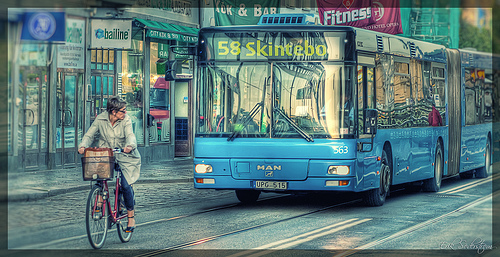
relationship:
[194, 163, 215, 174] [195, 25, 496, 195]
light on bus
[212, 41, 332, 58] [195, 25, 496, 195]
yellow letters on bus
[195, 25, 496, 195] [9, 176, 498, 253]
bus driving on road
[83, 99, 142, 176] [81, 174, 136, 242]
woman riding on a bike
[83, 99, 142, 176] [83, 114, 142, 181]
woman wearing a tan jacket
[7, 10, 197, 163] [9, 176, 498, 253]
shops along road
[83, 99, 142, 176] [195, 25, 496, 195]
woman in front of bus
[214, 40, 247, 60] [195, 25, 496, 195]
number on bus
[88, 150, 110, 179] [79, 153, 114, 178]
bag in bike basket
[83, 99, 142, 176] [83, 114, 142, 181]
woman wearing a tan coat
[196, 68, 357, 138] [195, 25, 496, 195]
windshield on bus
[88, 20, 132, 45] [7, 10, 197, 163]
sign on shops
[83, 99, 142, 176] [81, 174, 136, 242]
woman riding red bike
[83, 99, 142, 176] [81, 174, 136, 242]
woman riding a bike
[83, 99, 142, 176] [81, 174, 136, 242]
woman riding a red bike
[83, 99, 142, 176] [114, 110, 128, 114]
woman wearing glasses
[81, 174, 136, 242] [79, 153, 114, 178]
bike with a basket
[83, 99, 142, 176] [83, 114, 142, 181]
woman wearing brown trench coat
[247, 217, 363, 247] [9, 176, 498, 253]
lines painted on road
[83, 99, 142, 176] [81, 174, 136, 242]
woman on a bike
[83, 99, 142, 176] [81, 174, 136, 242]
woman riding her bike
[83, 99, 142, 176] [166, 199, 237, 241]
woman on tracks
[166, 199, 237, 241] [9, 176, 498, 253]
tracks on ground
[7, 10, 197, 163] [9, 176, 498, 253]
shops along side road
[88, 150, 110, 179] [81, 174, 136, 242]
bag in front of bike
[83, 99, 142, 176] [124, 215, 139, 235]
woman wearing high heels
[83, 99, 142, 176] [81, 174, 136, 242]
woman in tan jacket on bike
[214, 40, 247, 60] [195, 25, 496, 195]
number 58 on bus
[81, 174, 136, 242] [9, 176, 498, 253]
bike on road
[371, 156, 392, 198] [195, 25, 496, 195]
tire on bus